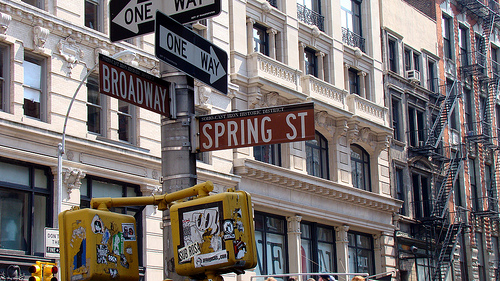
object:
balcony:
[245, 0, 300, 92]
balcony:
[298, 20, 348, 116]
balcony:
[342, 45, 389, 128]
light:
[56, 48, 141, 279]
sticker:
[174, 240, 203, 263]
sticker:
[193, 249, 230, 268]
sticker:
[231, 233, 248, 260]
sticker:
[175, 215, 192, 242]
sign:
[161, 180, 261, 277]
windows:
[248, 16, 374, 111]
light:
[167, 190, 257, 274]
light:
[55, 202, 145, 278]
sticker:
[179, 200, 225, 261]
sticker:
[222, 218, 235, 241]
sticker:
[96, 244, 117, 265]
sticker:
[117, 219, 136, 239]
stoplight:
[15, 222, 72, 279]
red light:
[46, 263, 61, 274]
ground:
[406, 120, 461, 154]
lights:
[119, 47, 144, 64]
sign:
[108, 0, 223, 44]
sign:
[95, 51, 174, 121]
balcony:
[253, 50, 393, 139]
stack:
[384, 27, 444, 217]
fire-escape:
[398, 77, 463, 279]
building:
[380, 0, 499, 281]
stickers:
[169, 187, 255, 277]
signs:
[94, 0, 323, 144]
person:
[3, 215, 17, 249]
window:
[1, 161, 53, 256]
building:
[2, 0, 499, 281]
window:
[351, 143, 375, 195]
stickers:
[56, 207, 137, 281]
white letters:
[101, 66, 174, 120]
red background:
[99, 61, 171, 116]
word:
[99, 61, 170, 116]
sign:
[179, 103, 339, 158]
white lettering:
[200, 113, 307, 149]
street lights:
[51, 179, 258, 281]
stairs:
[418, 1, 495, 276]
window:
[336, 134, 380, 205]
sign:
[154, 10, 229, 95]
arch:
[350, 142, 371, 164]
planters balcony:
[297, 3, 377, 63]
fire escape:
[401, 0, 500, 280]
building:
[246, 0, 393, 281]